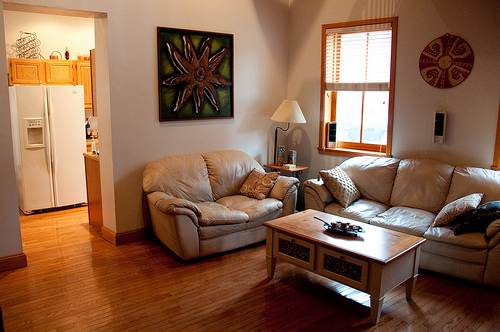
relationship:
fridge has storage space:
[8, 83, 90, 215] [9, 57, 77, 87]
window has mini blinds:
[319, 17, 399, 157] [323, 21, 396, 91]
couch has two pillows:
[141, 150, 499, 288] [430, 188, 500, 235]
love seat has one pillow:
[144, 148, 301, 260] [237, 166, 282, 200]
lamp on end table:
[268, 95, 311, 167] [262, 159, 310, 178]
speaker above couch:
[431, 110, 448, 144] [141, 150, 499, 288]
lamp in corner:
[268, 95, 311, 167] [258, 1, 312, 217]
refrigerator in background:
[8, 83, 90, 215] [2, 0, 120, 272]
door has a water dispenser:
[13, 85, 57, 213] [24, 118, 46, 148]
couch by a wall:
[141, 150, 499, 288] [107, 1, 500, 247]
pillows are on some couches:
[238, 165, 500, 236] [141, 150, 499, 288]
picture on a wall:
[157, 26, 234, 121] [107, 1, 500, 247]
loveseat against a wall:
[144, 148, 301, 260] [107, 1, 500, 247]